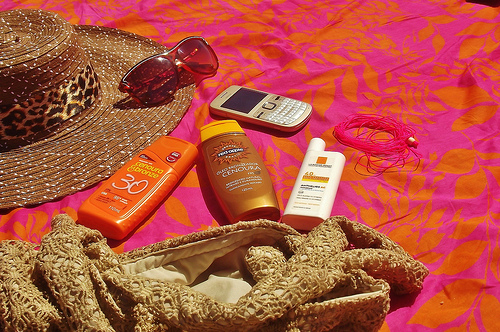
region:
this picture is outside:
[9, 22, 499, 300]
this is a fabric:
[50, 226, 287, 329]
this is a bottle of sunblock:
[100, 135, 187, 230]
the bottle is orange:
[80, 147, 190, 269]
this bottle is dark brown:
[195, 144, 280, 224]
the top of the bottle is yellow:
[201, 117, 243, 134]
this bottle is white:
[295, 132, 333, 221]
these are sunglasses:
[126, 40, 226, 97]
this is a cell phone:
[202, 61, 302, 157]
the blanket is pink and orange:
[230, 7, 498, 193]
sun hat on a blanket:
[18, 15, 84, 180]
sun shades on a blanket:
[155, 30, 230, 76]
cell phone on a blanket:
[215, 68, 305, 114]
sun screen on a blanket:
[280, 135, 337, 225]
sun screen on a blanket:
[195, 120, 271, 218]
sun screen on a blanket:
[158, 128, 194, 186]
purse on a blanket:
[295, 231, 416, 306]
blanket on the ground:
[368, 25, 478, 88]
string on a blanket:
[355, 106, 423, 169]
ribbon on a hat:
[32, 74, 99, 114]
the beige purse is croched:
[7, 229, 411, 315]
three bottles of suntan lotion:
[86, 116, 343, 223]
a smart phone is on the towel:
[208, 78, 316, 130]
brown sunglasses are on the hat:
[116, 38, 218, 108]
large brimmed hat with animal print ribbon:
[11, 5, 188, 175]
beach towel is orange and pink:
[276, 4, 473, 109]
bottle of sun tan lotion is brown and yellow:
[193, 116, 284, 218]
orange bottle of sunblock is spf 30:
[71, 137, 199, 205]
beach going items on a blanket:
[15, 15, 357, 294]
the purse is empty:
[146, 255, 257, 280]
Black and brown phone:
[199, 79, 315, 144]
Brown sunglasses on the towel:
[107, 35, 237, 115]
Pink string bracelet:
[323, 80, 428, 242]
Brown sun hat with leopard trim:
[3, 9, 215, 214]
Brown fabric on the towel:
[1, 204, 471, 328]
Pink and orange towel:
[2, 0, 499, 330]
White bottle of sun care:
[282, 132, 362, 221]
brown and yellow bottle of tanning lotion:
[195, 105, 289, 242]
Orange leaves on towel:
[289, 45, 395, 129]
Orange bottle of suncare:
[57, 105, 225, 254]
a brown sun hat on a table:
[1, 11, 218, 202]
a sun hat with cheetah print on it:
[1, 0, 193, 180]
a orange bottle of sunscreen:
[64, 119, 199, 248]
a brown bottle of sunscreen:
[178, 111, 321, 249]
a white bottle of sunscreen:
[273, 122, 375, 254]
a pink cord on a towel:
[300, 94, 470, 234]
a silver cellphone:
[198, 63, 368, 172]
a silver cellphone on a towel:
[205, 73, 385, 174]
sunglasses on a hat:
[109, 30, 248, 111]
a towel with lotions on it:
[13, 27, 389, 325]